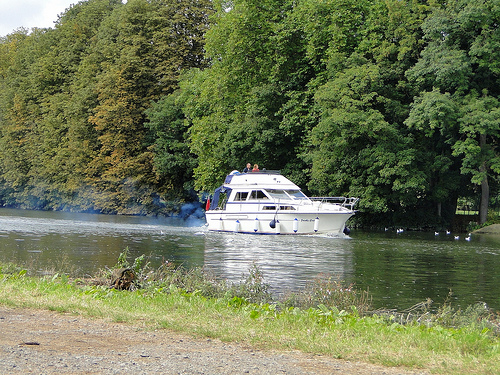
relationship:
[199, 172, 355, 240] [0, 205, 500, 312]
boat on river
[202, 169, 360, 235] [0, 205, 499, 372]
boat on river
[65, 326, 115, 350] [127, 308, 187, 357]
rocks on ground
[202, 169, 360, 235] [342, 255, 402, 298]
boat in water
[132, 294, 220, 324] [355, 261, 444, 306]
grass at edge of water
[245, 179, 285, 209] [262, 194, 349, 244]
window on boat